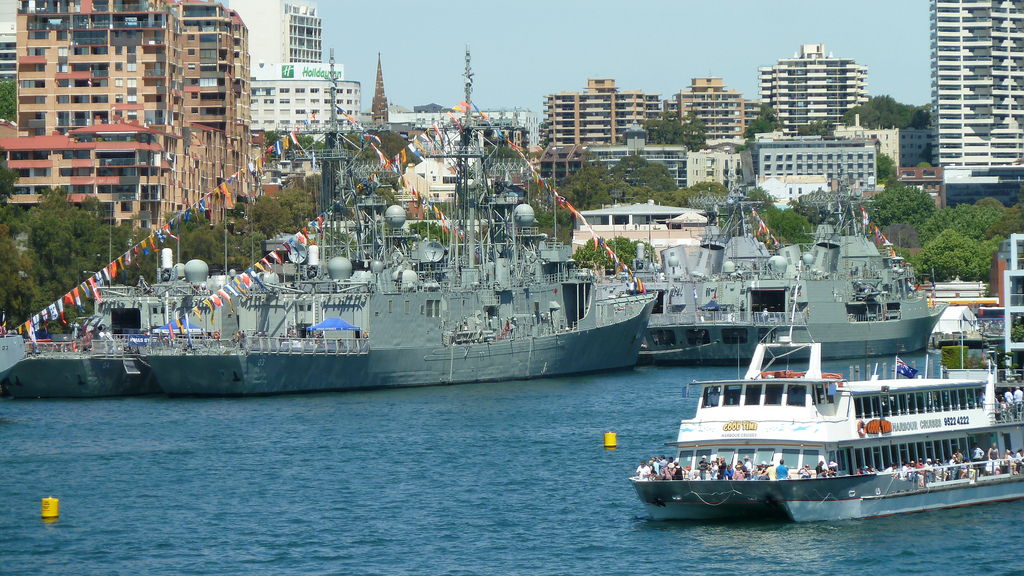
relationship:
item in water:
[40, 494, 58, 516] [3, 336, 1004, 561]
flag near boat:
[894, 360, 916, 380] [625, 320, 1021, 524]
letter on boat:
[946, 416, 972, 427] [631, 327, 1018, 511]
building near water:
[1, 3, 256, 237] [3, 336, 1004, 561]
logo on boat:
[856, 402, 900, 452] [625, 320, 1021, 524]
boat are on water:
[625, 338, 1024, 526] [3, 336, 1004, 561]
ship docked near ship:
[64, 117, 412, 409] [640, 203, 939, 370]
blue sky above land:
[323, 0, 934, 117] [8, 197, 1020, 331]